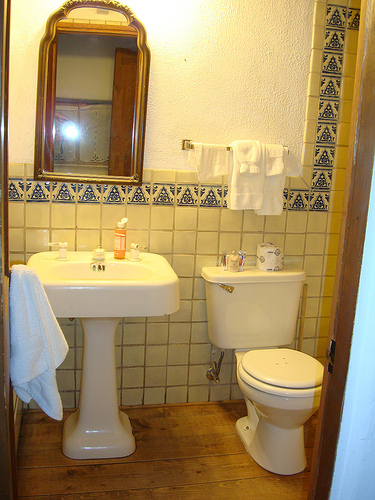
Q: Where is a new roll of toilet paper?
A: Toilet tank.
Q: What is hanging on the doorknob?
A: White towel.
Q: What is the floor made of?
A: Wood.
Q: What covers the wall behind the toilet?
A: Tile.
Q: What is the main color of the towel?
A: White.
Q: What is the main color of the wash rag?
A: White.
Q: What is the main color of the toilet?
A: White.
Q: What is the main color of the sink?
A: White.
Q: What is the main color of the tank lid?
A: White.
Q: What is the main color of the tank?
A: White.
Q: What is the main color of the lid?
A: White.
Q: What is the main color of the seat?
A: White.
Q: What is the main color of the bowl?
A: White.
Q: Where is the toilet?
A: Under the towel rack.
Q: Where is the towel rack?
A: Over the toilet.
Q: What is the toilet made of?
A: Porcelain.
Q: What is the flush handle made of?
A: Metal.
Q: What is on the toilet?
A: A roll of toilet paper.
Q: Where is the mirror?
A: Over the sink.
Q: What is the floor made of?
A: Wood.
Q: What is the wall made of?
A: Tile.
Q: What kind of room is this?
A: Bathroom.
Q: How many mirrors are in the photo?
A: One.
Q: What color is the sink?
A: White.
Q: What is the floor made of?
A: Wood.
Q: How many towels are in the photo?
A: Three.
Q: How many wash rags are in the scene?
A: Three.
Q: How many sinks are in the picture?
A: One.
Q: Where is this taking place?
A: In a bathroom.